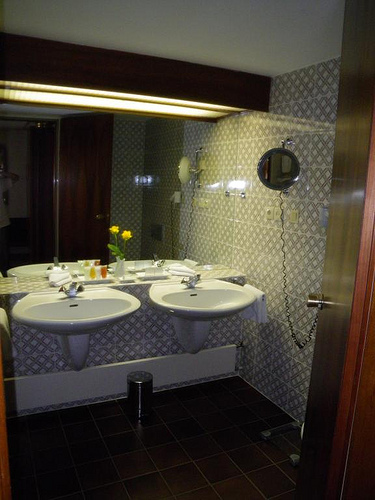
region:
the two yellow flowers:
[109, 224, 132, 278]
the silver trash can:
[124, 369, 151, 420]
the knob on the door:
[303, 289, 323, 312]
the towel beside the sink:
[242, 281, 272, 325]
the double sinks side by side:
[21, 278, 258, 349]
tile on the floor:
[13, 372, 296, 491]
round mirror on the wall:
[258, 149, 300, 201]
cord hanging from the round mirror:
[271, 192, 327, 360]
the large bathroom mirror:
[9, 117, 234, 271]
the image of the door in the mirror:
[61, 119, 108, 269]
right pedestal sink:
[149, 277, 256, 355]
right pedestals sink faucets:
[180, 270, 201, 291]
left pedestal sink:
[11, 279, 135, 369]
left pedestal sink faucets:
[57, 278, 85, 297]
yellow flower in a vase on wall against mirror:
[119, 223, 131, 281]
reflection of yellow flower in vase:
[104, 222, 123, 282]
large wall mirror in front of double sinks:
[2, 100, 243, 275]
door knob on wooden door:
[306, 296, 323, 307]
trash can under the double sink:
[125, 365, 157, 423]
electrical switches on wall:
[259, 202, 299, 227]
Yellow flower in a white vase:
[106, 229, 132, 279]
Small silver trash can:
[125, 369, 153, 428]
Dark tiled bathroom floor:
[9, 370, 306, 499]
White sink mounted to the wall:
[148, 273, 256, 354]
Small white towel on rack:
[239, 283, 269, 324]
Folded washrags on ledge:
[48, 269, 73, 288]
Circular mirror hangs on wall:
[255, 147, 300, 190]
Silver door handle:
[304, 290, 325, 311]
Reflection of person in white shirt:
[0, 164, 21, 278]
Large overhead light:
[0, 28, 273, 122]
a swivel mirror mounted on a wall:
[258, 149, 301, 185]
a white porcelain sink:
[145, 276, 254, 353]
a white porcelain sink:
[12, 285, 137, 370]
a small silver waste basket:
[126, 369, 153, 419]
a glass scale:
[259, 420, 305, 468]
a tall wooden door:
[298, 0, 369, 498]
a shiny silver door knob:
[304, 293, 323, 310]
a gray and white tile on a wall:
[269, 346, 293, 384]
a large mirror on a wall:
[0, 99, 238, 270]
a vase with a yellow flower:
[117, 230, 129, 277]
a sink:
[163, 281, 245, 314]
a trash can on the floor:
[128, 371, 158, 405]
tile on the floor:
[66, 444, 249, 493]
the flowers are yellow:
[109, 221, 137, 247]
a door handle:
[301, 288, 319, 309]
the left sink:
[25, 292, 124, 324]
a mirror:
[252, 146, 302, 194]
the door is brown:
[315, 333, 347, 383]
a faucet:
[62, 280, 92, 295]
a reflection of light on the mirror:
[226, 168, 250, 195]